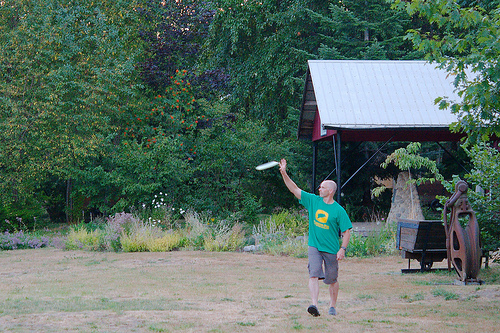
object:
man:
[278, 157, 354, 317]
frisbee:
[255, 161, 279, 171]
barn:
[295, 59, 499, 204]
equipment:
[395, 180, 484, 286]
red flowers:
[123, 61, 209, 164]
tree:
[0, 1, 211, 233]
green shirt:
[298, 189, 353, 254]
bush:
[142, 192, 186, 252]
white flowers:
[142, 192, 186, 227]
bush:
[0, 217, 51, 250]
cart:
[396, 219, 448, 273]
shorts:
[307, 246, 340, 286]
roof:
[297, 58, 498, 142]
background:
[0, 3, 499, 240]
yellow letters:
[314, 220, 330, 229]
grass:
[63, 211, 390, 257]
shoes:
[307, 304, 338, 317]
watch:
[340, 246, 346, 251]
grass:
[4, 251, 429, 330]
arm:
[281, 172, 315, 206]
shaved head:
[322, 180, 338, 195]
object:
[384, 170, 426, 228]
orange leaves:
[120, 235, 238, 252]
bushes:
[72, 192, 249, 253]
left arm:
[339, 211, 352, 250]